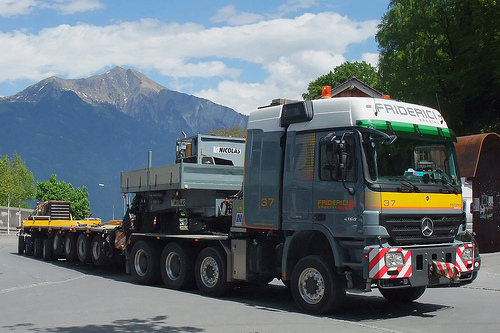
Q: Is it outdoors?
A: Yes, it is outdoors.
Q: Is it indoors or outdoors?
A: It is outdoors.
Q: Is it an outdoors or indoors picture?
A: It is outdoors.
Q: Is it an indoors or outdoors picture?
A: It is outdoors.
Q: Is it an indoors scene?
A: No, it is outdoors.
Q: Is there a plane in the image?
A: No, there are no airplanes.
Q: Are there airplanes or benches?
A: No, there are no airplanes or benches.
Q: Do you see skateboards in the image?
A: No, there are no skateboards.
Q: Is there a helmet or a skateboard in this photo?
A: No, there are no skateboards or helmets.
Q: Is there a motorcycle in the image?
A: No, there are no motorcycles.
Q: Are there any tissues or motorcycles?
A: No, there are no motorcycles or tissues.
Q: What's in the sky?
A: The clouds are in the sky.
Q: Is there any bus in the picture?
A: No, there are no buses.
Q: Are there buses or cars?
A: No, there are no buses or cars.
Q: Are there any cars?
A: No, there are no cars.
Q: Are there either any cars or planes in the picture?
A: No, there are no cars or planes.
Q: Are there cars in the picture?
A: No, there are no cars.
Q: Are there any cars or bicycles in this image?
A: No, there are no cars or bicycles.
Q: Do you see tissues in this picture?
A: No, there are no tissues.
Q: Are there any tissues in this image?
A: No, there are no tissues.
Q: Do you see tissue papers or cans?
A: No, there are no tissue papers or cans.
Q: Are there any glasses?
A: No, there are no glasses.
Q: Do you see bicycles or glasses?
A: No, there are no glasses or bicycles.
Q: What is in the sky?
A: The clouds are in the sky.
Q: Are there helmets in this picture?
A: No, there are no helmets.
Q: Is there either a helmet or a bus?
A: No, there are no helmets or buses.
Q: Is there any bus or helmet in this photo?
A: No, there are no helmets or buses.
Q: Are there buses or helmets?
A: No, there are no helmets or buses.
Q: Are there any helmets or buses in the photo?
A: No, there are no helmets or buses.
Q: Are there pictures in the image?
A: No, there are no pictures.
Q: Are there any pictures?
A: No, there are no pictures.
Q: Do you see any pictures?
A: No, there are no pictures.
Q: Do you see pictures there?
A: No, there are no pictures.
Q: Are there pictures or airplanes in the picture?
A: No, there are no pictures or airplanes.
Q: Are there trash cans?
A: No, there are no trash cans.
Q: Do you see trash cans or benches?
A: No, there are no trash cans or benches.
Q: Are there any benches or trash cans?
A: No, there are no trash cans or benches.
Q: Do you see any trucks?
A: Yes, there is a truck.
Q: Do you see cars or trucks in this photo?
A: Yes, there is a truck.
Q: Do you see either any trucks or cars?
A: Yes, there is a truck.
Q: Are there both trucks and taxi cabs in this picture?
A: No, there is a truck but no taxis.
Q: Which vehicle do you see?
A: The vehicle is a truck.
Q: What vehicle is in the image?
A: The vehicle is a truck.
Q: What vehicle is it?
A: The vehicle is a truck.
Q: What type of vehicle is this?
A: This is a truck.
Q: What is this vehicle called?
A: This is a truck.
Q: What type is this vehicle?
A: This is a truck.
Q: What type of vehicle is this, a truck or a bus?
A: This is a truck.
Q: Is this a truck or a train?
A: This is a truck.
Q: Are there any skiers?
A: No, there are no skiers.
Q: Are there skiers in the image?
A: No, there are no skiers.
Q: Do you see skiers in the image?
A: No, there are no skiers.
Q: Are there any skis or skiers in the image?
A: No, there are no skiers or skis.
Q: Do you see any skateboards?
A: No, there are no skateboards.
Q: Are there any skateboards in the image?
A: No, there are no skateboards.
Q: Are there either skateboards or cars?
A: No, there are no skateboards or cars.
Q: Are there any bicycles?
A: No, there are no bicycles.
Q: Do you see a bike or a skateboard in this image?
A: No, there are no bikes or skateboards.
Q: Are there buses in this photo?
A: No, there are no buses.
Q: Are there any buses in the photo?
A: No, there are no buses.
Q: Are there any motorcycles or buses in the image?
A: No, there are no buses or motorcycles.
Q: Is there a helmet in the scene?
A: No, there are no helmets.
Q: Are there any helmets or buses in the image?
A: No, there are no helmets or buses.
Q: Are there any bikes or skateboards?
A: No, there are no bikes or skateboards.